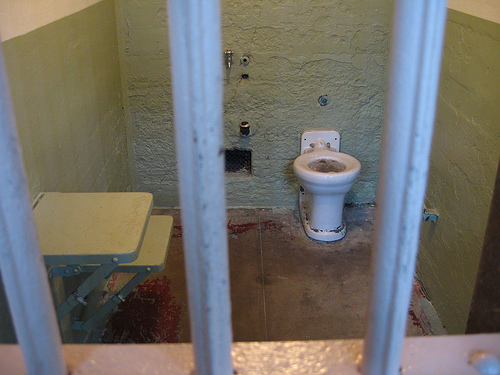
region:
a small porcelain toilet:
[293, 130, 357, 242]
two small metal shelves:
[26, 190, 173, 321]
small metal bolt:
[110, 256, 118, 263]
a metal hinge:
[46, 263, 110, 323]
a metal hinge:
[80, 270, 150, 334]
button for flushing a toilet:
[318, 95, 329, 106]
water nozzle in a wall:
[223, 48, 235, 70]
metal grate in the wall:
[222, 149, 247, 173]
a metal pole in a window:
[167, 0, 229, 374]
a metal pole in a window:
[366, 3, 444, 373]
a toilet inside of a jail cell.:
[272, 68, 374, 253]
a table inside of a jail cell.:
[0, 143, 217, 338]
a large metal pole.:
[159, 0, 274, 371]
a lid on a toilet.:
[287, 140, 377, 192]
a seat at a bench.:
[100, 179, 187, 299]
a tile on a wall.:
[84, 88, 106, 117]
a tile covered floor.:
[74, 197, 448, 344]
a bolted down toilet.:
[293, 198, 361, 246]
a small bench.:
[15, 157, 205, 307]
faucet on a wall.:
[224, 45, 276, 85]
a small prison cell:
[0, 3, 490, 373]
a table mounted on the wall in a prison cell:
[11, 157, 179, 327]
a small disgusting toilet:
[283, 123, 369, 245]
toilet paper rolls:
[413, 195, 449, 233]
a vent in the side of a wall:
[225, 145, 256, 177]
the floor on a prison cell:
[74, 208, 449, 333]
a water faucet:
[222, 49, 236, 74]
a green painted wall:
[111, 0, 378, 210]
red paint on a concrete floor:
[93, 275, 180, 341]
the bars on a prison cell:
[160, 5, 455, 372]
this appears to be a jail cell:
[19, 8, 496, 369]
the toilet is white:
[293, 118, 363, 245]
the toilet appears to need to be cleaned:
[298, 113, 361, 244]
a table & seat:
[28, 169, 184, 331]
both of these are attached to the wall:
[13, 167, 180, 337]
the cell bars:
[1, 109, 498, 371]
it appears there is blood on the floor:
[141, 216, 282, 345]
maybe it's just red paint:
[118, 207, 274, 339]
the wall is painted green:
[48, 40, 120, 135]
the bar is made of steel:
[362, 8, 438, 370]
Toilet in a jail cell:
[291, 130, 362, 242]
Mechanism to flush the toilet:
[316, 94, 329, 107]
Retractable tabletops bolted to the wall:
[29, 189, 174, 344]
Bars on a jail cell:
[2, 1, 499, 373]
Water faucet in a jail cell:
[224, 48, 233, 69]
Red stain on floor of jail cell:
[225, 218, 285, 235]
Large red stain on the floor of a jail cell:
[96, 274, 183, 345]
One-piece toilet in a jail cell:
[292, 128, 361, 241]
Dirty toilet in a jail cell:
[291, 127, 362, 242]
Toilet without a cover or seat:
[291, 128, 361, 240]